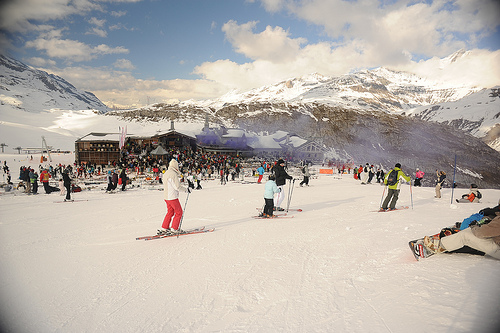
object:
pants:
[261, 196, 275, 216]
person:
[377, 161, 407, 212]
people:
[3, 164, 134, 203]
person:
[273, 159, 293, 207]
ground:
[0, 152, 498, 331]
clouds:
[246, 27, 299, 56]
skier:
[62, 164, 76, 200]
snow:
[0, 160, 499, 329]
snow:
[267, 223, 402, 290]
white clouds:
[9, 5, 106, 42]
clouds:
[222, 0, 499, 89]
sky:
[0, 2, 497, 113]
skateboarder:
[402, 208, 499, 268]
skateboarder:
[448, 182, 492, 211]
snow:
[0, 60, 499, 185]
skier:
[413, 167, 424, 185]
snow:
[0, 48, 498, 330]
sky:
[122, 11, 228, 56]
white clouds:
[227, 21, 386, 70]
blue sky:
[147, 1, 204, 58]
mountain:
[2, 27, 499, 189]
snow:
[148, 42, 498, 147]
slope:
[1, 169, 498, 331]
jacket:
[148, 165, 192, 204]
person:
[158, 152, 196, 225]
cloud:
[206, 19, 217, 32]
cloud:
[177, 57, 182, 67]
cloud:
[111, 57, 141, 72]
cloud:
[81, 24, 110, 40]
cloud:
[220, 19, 308, 66]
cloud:
[259, 0, 285, 13]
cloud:
[287, 2, 390, 46]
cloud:
[380, 4, 444, 57]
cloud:
[434, 32, 465, 59]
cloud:
[44, 27, 61, 37]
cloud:
[85, 15, 105, 26]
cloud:
[87, 28, 107, 38]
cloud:
[21, 37, 94, 62]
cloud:
[30, 54, 47, 66]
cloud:
[438, 9, 485, 37]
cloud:
[467, 31, 481, 45]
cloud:
[386, 4, 439, 58]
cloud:
[430, 0, 448, 10]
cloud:
[440, 32, 455, 42]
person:
[261, 173, 282, 220]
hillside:
[138, 188, 228, 259]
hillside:
[6, 156, 497, 331]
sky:
[8, 5, 481, 130]